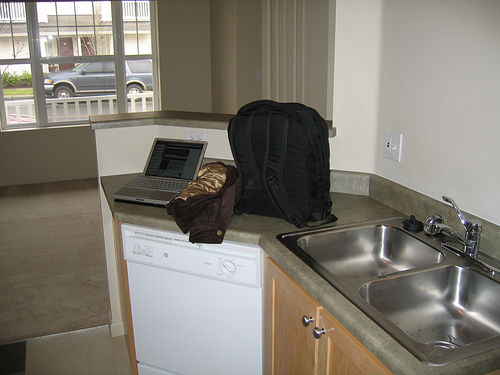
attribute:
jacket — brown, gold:
[165, 159, 238, 246]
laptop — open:
[115, 126, 205, 224]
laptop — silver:
[124, 142, 184, 202]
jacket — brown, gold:
[160, 171, 247, 240]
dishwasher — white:
[113, 244, 250, 353]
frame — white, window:
[43, 33, 155, 116]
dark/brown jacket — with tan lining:
[167, 158, 239, 244]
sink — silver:
[306, 224, 484, 356]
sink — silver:
[268, 194, 498, 368]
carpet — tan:
[1, 186, 106, 320]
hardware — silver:
[300, 316, 323, 341]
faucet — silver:
[428, 213, 478, 259]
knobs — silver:
[298, 310, 332, 339]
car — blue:
[41, 56, 157, 99]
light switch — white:
[385, 128, 403, 166]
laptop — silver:
[115, 138, 208, 210]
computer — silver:
[116, 138, 206, 212]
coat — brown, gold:
[170, 160, 237, 253]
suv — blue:
[44, 55, 154, 104]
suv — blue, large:
[39, 52, 157, 105]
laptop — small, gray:
[112, 133, 209, 210]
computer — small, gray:
[110, 132, 207, 212]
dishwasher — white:
[119, 222, 266, 372]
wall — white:
[325, 2, 497, 228]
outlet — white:
[384, 132, 402, 165]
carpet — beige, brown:
[4, 179, 108, 342]